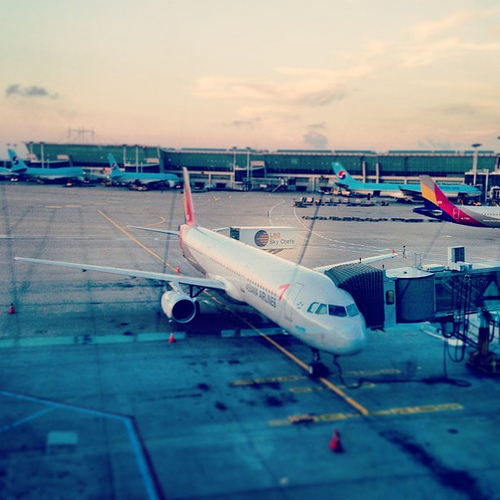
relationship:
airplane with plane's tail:
[13, 153, 412, 385] [178, 165, 196, 226]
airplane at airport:
[325, 156, 485, 213] [2, 135, 499, 495]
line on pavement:
[92, 207, 372, 422] [0, 167, 497, 496]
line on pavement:
[134, 209, 170, 229] [0, 167, 497, 496]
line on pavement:
[273, 400, 465, 427] [0, 167, 497, 496]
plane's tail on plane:
[415, 170, 457, 218] [409, 165, 498, 225]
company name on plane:
[249, 280, 277, 313] [9, 163, 396, 355]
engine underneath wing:
[154, 275, 199, 326] [7, 249, 239, 325]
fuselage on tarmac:
[172, 220, 374, 360] [0, 182, 500, 498]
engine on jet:
[154, 275, 199, 326] [16, 169, 398, 379]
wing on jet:
[4, 160, 417, 386] [14, 253, 224, 293]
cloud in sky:
[6, 82, 60, 100] [0, 2, 499, 152]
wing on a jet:
[176, 167, 198, 233] [147, 151, 379, 385]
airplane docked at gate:
[13, 165, 400, 381] [334, 247, 497, 381]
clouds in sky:
[197, 66, 351, 106] [15, 11, 194, 56]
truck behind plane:
[215, 223, 297, 252] [13, 166, 396, 381]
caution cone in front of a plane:
[327, 424, 347, 456] [13, 166, 396, 381]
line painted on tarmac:
[96, 208, 179, 273] [5, 137, 495, 497]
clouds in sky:
[197, 66, 351, 106] [25, 9, 470, 133]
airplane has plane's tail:
[325, 156, 485, 213] [328, 162, 360, 184]